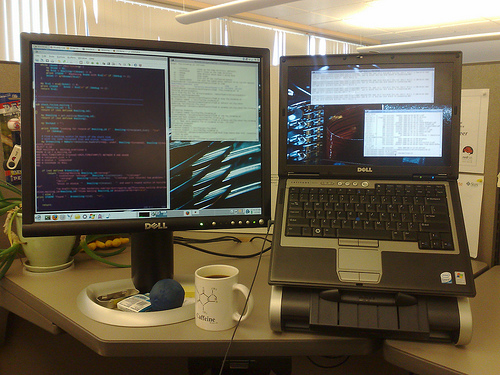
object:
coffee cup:
[193, 264, 254, 332]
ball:
[149, 278, 185, 311]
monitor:
[20, 32, 272, 238]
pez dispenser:
[1, 92, 23, 183]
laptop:
[267, 50, 478, 296]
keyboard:
[281, 178, 460, 255]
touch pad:
[335, 248, 383, 273]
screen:
[286, 63, 452, 167]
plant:
[0, 179, 132, 279]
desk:
[0, 233, 499, 375]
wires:
[171, 235, 274, 259]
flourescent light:
[332, 0, 499, 33]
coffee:
[203, 273, 228, 279]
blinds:
[0, 0, 370, 64]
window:
[1, 0, 379, 62]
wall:
[0, 61, 499, 265]